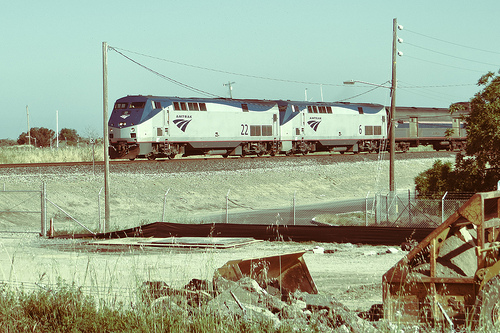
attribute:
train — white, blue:
[106, 92, 499, 163]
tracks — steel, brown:
[3, 145, 497, 171]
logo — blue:
[170, 113, 194, 131]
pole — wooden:
[101, 42, 111, 235]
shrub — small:
[410, 156, 452, 215]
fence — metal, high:
[1, 183, 499, 242]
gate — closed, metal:
[1, 184, 44, 237]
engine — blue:
[105, 90, 391, 146]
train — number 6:
[276, 96, 393, 144]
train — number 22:
[104, 90, 281, 158]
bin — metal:
[204, 245, 322, 320]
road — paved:
[3, 230, 441, 322]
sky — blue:
[2, 1, 498, 104]